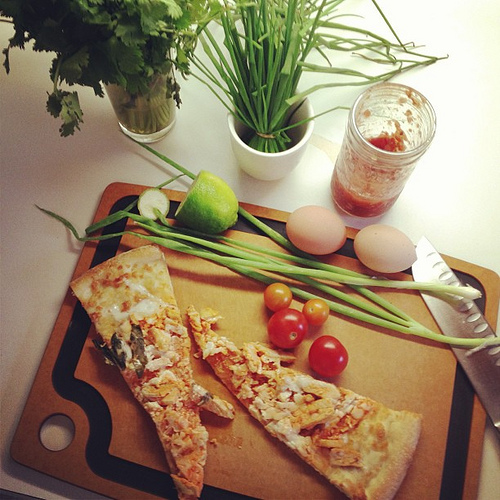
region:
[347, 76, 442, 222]
clear glass jar with pizza sauce in it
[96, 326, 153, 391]
cooked mushroom on pizza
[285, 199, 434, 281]
two eggs with brown shells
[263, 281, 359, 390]
four red tomatoes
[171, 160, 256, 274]
green lime that has been cut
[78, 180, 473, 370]
fresh green onions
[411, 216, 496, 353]
end of chopping knife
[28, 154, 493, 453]
wooden chopping board with black stripe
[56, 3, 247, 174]
glass jar holding herbs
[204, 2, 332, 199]
white coffee cup holding herbs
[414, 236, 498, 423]
silver knife blade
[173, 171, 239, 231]
lime with piece sliced off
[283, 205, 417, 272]
two brown eggs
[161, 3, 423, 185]
white cup with greenery in it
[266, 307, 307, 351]
bright red cherry tomato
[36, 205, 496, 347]
two green onions on cutting board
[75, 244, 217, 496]
slice of pizza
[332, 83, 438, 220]
mostly empty jar with red stuff in it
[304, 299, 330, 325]
smaller orange cherry tomato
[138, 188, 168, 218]
part of lime peel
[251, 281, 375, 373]
Red round tomatoes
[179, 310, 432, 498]
Slice of pizza on a tray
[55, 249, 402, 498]
Two slices of pizza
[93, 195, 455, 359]
Onions on a tray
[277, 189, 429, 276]
Two eggs on a tray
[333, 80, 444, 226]
Jar of salsa on a counter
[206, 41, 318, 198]
Chives in a bowel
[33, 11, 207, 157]
Parsley in a bowel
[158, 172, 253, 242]
Lime on a tray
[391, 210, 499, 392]
Knife on a tray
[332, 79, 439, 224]
glass jar of tomato-base food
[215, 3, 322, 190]
chives in container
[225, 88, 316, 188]
white porcelain cup holding veg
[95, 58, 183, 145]
clear glass vase holding cilantro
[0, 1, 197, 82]
cilantro in clear vase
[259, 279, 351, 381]
4 cherry tomatoes on cutting board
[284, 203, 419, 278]
2 chicken eggs on board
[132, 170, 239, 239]
cut green lime on board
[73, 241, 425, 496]
2 slices of pizza on board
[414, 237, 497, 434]
serrated steel knife blade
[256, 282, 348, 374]
four cherry tomatoes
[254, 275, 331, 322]
two cherry tomatoes are orange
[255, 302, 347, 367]
two cherry tomatoes are red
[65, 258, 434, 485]
two slices of pizza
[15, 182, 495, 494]
the pizza is on a cutting board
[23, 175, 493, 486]
the cuttig board is wooden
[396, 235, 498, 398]
a sharp knife is laying on the cutting board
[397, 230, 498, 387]
the knife is silver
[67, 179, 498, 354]
a pile of green onions